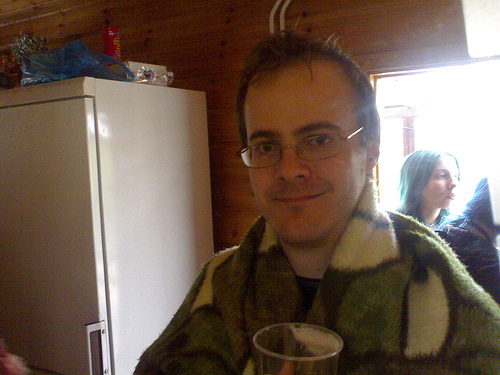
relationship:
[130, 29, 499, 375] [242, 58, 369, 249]
man has face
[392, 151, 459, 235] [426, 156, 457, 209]
woman has face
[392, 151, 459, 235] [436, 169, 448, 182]
woman has right eye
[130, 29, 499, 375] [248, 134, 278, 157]
man has right eye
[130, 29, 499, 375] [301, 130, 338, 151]
man has left eye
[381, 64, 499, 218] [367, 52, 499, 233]
light coming in window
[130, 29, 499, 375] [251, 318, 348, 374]
man holding mug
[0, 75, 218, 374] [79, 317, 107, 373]
refrigerator has handle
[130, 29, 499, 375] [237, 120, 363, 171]
man wearing glasses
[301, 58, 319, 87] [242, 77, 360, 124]
hair hanging on forehead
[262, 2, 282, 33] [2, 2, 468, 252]
cord attached to wall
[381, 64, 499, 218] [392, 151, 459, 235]
light reflects on woman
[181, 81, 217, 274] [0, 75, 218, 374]
shadow on side of refrigerator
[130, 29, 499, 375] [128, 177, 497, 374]
man wearing blanket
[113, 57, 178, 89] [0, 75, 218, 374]
item on top of refrigerator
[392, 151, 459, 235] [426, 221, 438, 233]
woman wearing necklace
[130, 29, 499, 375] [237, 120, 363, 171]
man with glasses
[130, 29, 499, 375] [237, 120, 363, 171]
man has glasses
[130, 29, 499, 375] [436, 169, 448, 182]
man has right eye